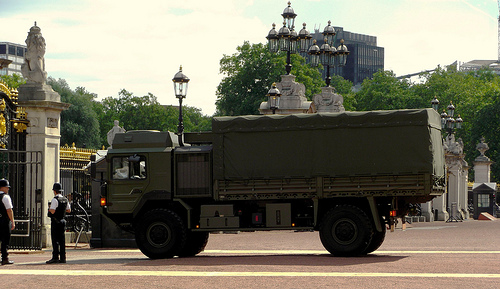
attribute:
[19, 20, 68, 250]
fence pillar — tall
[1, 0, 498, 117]
sky — blue, cloud filled